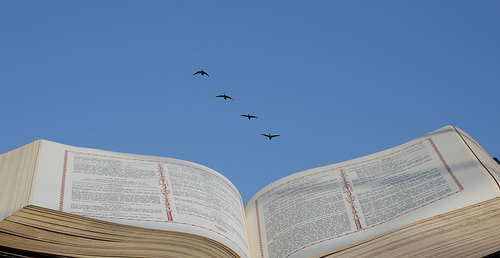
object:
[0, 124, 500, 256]
book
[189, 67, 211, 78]
bird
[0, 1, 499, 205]
sky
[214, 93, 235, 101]
birds